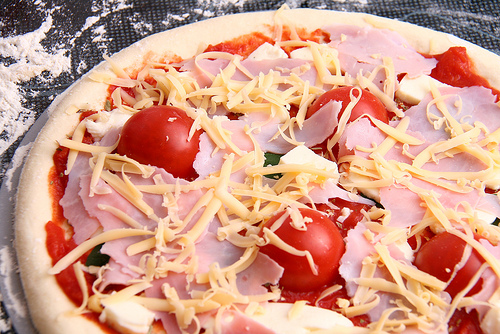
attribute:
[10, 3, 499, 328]
pizza — uncooked, round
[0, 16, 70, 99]
flour — white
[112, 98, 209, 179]
cherry tomato — ripe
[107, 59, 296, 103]
cheese — shredded, yellow, orange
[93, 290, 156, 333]
cheese — white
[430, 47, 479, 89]
tomato sauce — red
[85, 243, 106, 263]
onion — green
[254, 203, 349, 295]
tomato — red, round, whole, cherry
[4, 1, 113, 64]
table — black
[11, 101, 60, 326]
dough — brown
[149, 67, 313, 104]
strips — yellow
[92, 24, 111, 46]
flour — white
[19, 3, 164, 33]
mat — black